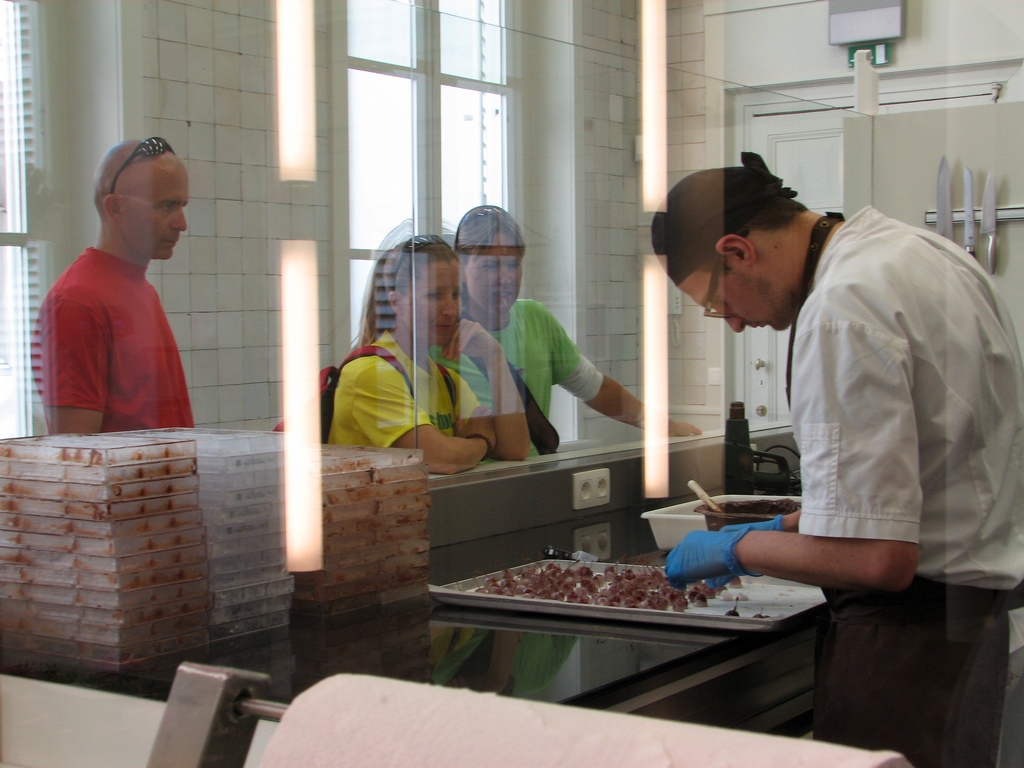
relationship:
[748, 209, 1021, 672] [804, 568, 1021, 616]
apron around waist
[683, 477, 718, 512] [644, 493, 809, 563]
handle coming out of bowl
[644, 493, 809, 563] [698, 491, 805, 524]
bowl of chocolate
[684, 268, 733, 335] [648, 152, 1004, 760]
sunglasses on man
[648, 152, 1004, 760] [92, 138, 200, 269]
man has head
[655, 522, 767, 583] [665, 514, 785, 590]
glove on glove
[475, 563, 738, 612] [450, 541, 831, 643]
food on tray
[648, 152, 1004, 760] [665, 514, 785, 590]
man wearing glove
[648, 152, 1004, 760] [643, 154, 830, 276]
man wearing head wrap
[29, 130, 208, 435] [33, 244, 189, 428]
man standing on shirt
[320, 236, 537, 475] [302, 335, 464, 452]
woman wears backpack